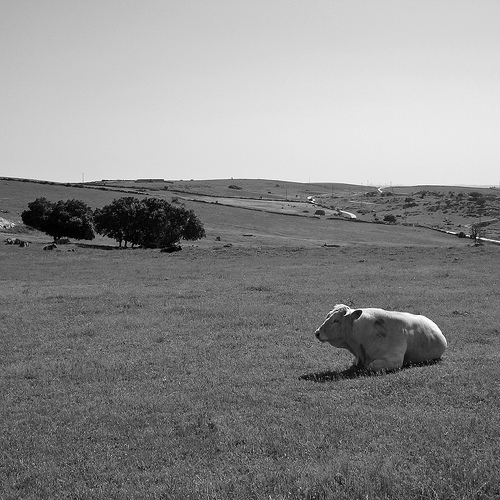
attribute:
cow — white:
[317, 302, 449, 370]